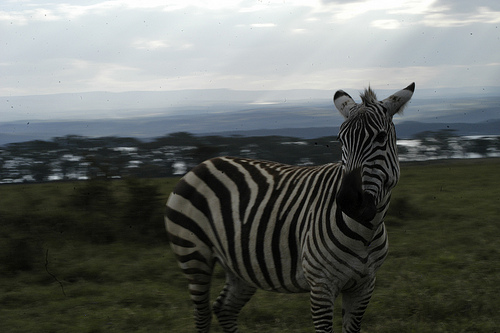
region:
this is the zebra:
[161, 80, 424, 317]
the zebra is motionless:
[162, 68, 419, 331]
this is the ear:
[328, 91, 359, 116]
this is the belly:
[225, 181, 310, 275]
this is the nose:
[332, 181, 372, 221]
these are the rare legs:
[193, 277, 262, 331]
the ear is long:
[390, 83, 419, 109]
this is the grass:
[53, 248, 138, 330]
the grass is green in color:
[98, 260, 145, 314]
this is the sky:
[198, 7, 299, 71]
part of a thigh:
[183, 245, 242, 308]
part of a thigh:
[184, 263, 215, 313]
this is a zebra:
[157, 77, 425, 324]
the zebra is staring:
[125, 80, 417, 327]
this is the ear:
[385, 75, 421, 110]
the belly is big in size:
[225, 209, 295, 266]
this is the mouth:
[339, 191, 377, 221]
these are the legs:
[187, 278, 254, 330]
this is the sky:
[87, 4, 222, 84]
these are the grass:
[80, 251, 152, 319]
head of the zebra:
[291, 52, 445, 223]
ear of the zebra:
[307, 85, 369, 141]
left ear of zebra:
[373, 70, 424, 127]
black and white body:
[211, 177, 323, 258]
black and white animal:
[143, 79, 442, 299]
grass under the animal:
[68, 265, 157, 330]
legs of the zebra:
[168, 263, 384, 325]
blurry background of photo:
[20, 119, 169, 197]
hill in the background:
[28, 76, 175, 137]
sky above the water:
[102, 12, 224, 65]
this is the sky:
[83, 7, 259, 133]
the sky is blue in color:
[377, 45, 466, 54]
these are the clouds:
[222, 12, 327, 59]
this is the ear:
[378, 87, 421, 113]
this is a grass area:
[407, 209, 471, 306]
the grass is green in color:
[392, 236, 460, 293]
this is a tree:
[122, 162, 157, 226]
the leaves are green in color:
[127, 188, 156, 215]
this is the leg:
[300, 277, 346, 324]